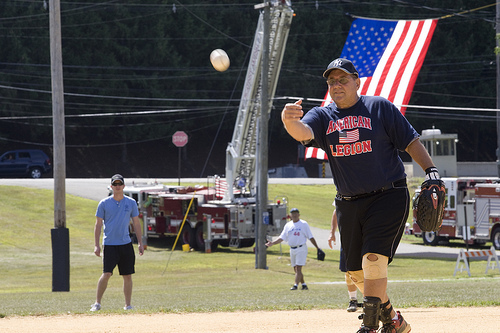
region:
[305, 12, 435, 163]
American flag flying in the distance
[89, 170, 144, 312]
man wearing blue shirt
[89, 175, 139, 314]
man wearing black shorts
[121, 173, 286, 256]
fire engine in the distance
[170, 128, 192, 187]
stop sign in the distance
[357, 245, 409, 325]
man wearing knee guards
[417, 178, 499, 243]
fire truck in the distance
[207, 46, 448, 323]
man throwing ball in air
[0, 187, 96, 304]
large grassy field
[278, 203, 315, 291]
man wearing white t-shirt and pants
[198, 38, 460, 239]
a man pitching a ball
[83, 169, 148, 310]
a man watching something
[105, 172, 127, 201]
a man wearing a baseball cap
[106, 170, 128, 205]
a man wearing sun glasses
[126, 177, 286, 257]
a red and white fire truck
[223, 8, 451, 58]
the American flag hanging from a firetruck ladder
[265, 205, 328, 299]
a man walking on the grass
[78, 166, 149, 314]
a man wearing black shorts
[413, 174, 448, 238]
a brown, black, and orange baseball mitt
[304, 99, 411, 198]
an American Legion t-shirt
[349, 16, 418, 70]
Part of American flag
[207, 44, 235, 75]
white baseball in mid air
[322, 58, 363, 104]
Heas of man who pitched ball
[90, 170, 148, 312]
Player watching the pitch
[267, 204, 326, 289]
Fielder watching the pitch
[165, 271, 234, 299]
Part of ball field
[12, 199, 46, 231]
Part of ball fielc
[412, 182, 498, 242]
truck parked near ball field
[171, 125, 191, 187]
Stop sign on nearby road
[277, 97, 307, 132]
Hand of man who pitched ball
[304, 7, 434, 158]
An American flag.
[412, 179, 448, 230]
A black baseball glove.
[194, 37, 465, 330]
A man throwing a baseball.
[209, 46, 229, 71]
A baseball.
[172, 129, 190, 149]
A red and white stop sign.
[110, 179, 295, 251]
A red firetruck.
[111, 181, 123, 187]
A black pair of sunglasses.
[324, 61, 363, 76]
A baseball cap.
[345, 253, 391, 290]
Brown knee bands.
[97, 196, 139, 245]
A short sleeved light blue shirt.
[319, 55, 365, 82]
hat on a persons head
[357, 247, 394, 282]
brace on a persons knee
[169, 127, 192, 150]
red and white sign on a pole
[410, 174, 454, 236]
baseball glove on a persons hand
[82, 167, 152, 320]
person with a blue shirt standing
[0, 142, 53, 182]
vehicle on a street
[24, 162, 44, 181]
rear wheel on a vehicle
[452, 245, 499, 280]
barricades on the ground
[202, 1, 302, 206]
ladder on a fire engine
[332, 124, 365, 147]
flag on a persons shirt